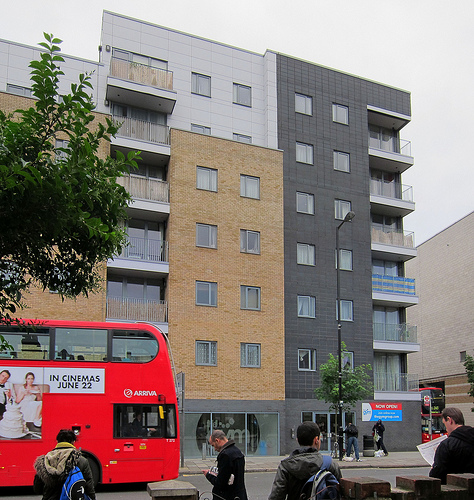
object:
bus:
[1, 315, 181, 489]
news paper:
[210, 465, 237, 488]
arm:
[206, 459, 235, 488]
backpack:
[61, 464, 88, 500]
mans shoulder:
[35, 428, 96, 499]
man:
[427, 408, 474, 486]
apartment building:
[277, 51, 424, 403]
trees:
[1, 31, 143, 319]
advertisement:
[0, 367, 105, 441]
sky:
[0, 0, 474, 249]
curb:
[180, 464, 207, 478]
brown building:
[168, 127, 285, 400]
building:
[277, 53, 424, 450]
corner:
[279, 53, 474, 452]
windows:
[293, 89, 314, 118]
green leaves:
[36, 40, 50, 51]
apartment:
[367, 109, 415, 173]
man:
[205, 429, 249, 500]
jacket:
[34, 449, 105, 498]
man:
[268, 421, 344, 499]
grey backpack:
[302, 449, 342, 500]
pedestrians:
[346, 417, 391, 457]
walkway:
[178, 449, 423, 468]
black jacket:
[427, 422, 474, 485]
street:
[0, 464, 429, 499]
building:
[99, 9, 422, 450]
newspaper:
[417, 433, 450, 466]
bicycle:
[329, 430, 357, 460]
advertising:
[362, 401, 404, 424]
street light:
[334, 211, 359, 459]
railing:
[368, 130, 413, 161]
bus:
[412, 385, 447, 445]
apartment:
[101, 10, 269, 117]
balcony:
[103, 55, 179, 115]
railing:
[110, 54, 173, 73]